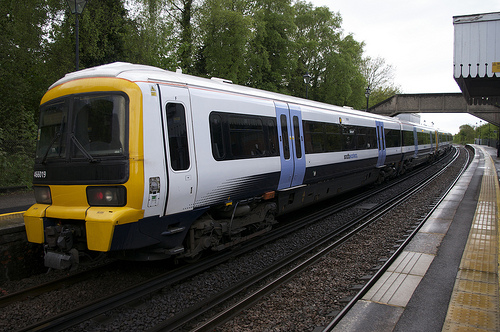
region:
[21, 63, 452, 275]
long white and yellow train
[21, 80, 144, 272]
train is yellow on end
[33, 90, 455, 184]
train has tinted windows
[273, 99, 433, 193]
train has blue doors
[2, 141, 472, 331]
two sets of train tracks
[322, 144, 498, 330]
platform to right of train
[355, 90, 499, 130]
walkway above train tracks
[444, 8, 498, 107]
awning above platform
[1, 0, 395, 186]
green trees behind train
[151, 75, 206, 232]
lone white door on train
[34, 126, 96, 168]
windshield wipers on train windows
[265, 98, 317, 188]
purple doors on train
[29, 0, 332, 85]
row of tall green trees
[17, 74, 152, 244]
front of train is yellow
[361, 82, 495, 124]
cement overpass over the train tracks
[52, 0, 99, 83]
old fashioned street light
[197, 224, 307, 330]
brown metal train tracks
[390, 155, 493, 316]
cement train platform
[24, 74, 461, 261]
large yellow and white passenger train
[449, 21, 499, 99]
white awning over train platform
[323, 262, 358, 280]
the gravel is brown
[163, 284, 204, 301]
the gravel is black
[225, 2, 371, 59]
the trees are tall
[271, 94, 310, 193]
the doors are blue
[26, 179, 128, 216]
the headlights are off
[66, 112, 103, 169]
the wiper is up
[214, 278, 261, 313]
the track is metal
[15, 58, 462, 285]
the train is long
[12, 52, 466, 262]
the train is white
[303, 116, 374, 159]
the windows are dark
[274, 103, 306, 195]
Double blue doors on train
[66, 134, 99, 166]
Windshield wipers on train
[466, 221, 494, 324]
Yellow tile safety line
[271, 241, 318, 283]
Long metal track rail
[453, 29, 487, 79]
White wood roof overhang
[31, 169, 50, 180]
White number on front of train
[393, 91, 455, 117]
Concrete walk bridge over train track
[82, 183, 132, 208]
Headlight on front of train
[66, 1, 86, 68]
Black metal light pole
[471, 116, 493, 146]
Group of light poles in distance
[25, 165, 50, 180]
The white numbers on the left side of the front of the train.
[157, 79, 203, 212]
The front white door on the side of the train.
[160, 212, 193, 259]
The steps below the white door on the side of the train.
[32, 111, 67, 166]
The left front window.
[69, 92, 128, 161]
The right front window.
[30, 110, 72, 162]
The windshield wiper on the left window.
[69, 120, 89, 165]
The windshield wiper on the right window.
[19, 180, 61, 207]
The left headlight on the front of the train.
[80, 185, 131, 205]
The right headlight on the front of the train.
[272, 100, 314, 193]
The set of blue doors closest to the front of the train.